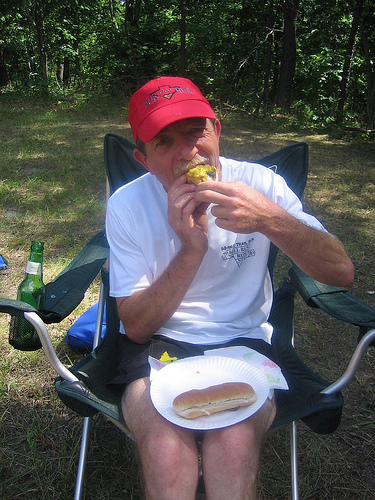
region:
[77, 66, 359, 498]
The man is sitting.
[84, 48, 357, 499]
The man is eating.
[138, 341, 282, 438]
A paper plate is on the man's lap.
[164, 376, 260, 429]
A hot dog bun is on the plate.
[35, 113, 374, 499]
The chair is green.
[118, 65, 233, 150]
The man wears a red cap.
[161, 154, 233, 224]
The man holds a piece of food.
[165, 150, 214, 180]
The man has a mustache.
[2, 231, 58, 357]
The chair holds a beer bottle.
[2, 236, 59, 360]
The bottle is green.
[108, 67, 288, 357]
man in red hat sitting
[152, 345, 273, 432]
white paper plate on lap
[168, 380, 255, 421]
hot dog bun on plate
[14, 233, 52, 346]
green bottle in cup holder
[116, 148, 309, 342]
white short sleeved tee shirt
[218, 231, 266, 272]
emblem on shirt chest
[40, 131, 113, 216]
green grass behind chair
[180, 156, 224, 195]
hands putting food in mouth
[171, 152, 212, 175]
mustache on man's face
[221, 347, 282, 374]
napkin under paper plate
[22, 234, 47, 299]
green glass beer bottle.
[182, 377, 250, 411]
hot dog bun on plate.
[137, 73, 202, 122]
red baseball cap on man's head.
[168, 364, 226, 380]
white paper plate on man's lap.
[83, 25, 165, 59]
green leaves on trees.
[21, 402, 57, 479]
green grass on ground.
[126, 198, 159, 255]
white t-shirt on man.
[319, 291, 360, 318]
arm rest on camping chair.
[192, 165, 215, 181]
hot dog that man is eating.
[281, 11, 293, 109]
part of tree trunk.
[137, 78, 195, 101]
blue logo on cap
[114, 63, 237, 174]
red cap with brim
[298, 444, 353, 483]
blades of brown grass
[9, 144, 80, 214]
sparse green grass on ground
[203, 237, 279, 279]
black symbol on shirt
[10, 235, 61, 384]
green bear bottle with white label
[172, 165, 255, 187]
man eating yellow food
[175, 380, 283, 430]
hot dog bun in plate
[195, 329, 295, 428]
white napkin with flower design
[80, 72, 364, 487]
man sitting in blue chair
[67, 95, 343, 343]
man eating hot dog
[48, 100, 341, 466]
man sitting on outdoor folding chair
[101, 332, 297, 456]
man with hot dog on a white paper plate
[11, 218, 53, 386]
green glass bottle in cup holder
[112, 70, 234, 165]
man with red baseball cap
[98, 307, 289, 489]
man wearing dark colored shorts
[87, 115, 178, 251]
man wearing white t shirt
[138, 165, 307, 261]
man holding hot dog with two hands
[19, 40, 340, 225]
man eating a hot dog in a park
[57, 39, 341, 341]
man eating hot dog at an outdoor picnic